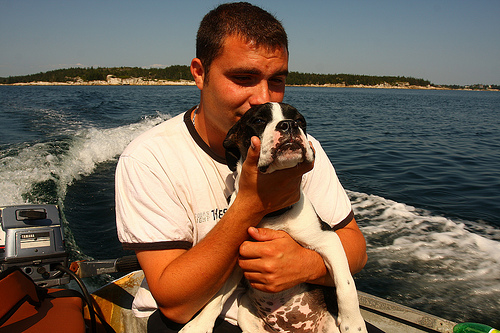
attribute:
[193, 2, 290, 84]
hair — short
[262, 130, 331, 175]
mouth — pink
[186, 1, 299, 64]
hair — black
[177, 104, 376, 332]
puppy — cute, white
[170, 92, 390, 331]
dog — black, white